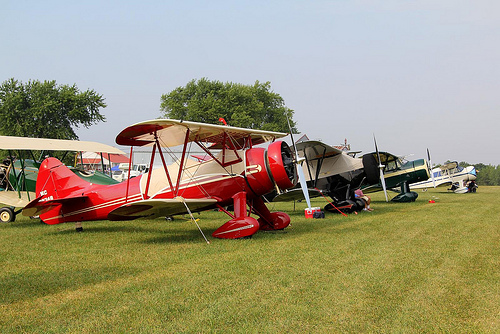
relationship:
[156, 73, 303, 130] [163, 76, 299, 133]
leaves on tree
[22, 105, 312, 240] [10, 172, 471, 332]
plane on ground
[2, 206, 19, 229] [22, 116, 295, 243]
back wheel on airplane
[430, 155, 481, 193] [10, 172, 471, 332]
airplane on ground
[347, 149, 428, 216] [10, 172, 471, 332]
airplane on ground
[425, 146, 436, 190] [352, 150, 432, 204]
propellor on airplane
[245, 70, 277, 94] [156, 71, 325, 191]
top of tree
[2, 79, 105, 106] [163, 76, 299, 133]
top of tree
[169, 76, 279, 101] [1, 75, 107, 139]
top of tree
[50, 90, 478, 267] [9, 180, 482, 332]
planes lined up on field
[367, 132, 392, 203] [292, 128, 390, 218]
propeller of plane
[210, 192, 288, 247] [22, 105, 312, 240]
landing gear of plane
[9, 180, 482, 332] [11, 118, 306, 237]
field of airplane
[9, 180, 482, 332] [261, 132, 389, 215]
field of planes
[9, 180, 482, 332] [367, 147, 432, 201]
field of airplane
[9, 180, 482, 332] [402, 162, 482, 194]
field of airplane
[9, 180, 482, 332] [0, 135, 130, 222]
field of airplane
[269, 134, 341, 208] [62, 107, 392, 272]
propeller on plane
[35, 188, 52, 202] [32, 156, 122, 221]
writing on tail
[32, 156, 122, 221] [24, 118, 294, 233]
tail of plane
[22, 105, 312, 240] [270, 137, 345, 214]
plane with propeller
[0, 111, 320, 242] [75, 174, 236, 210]
plane with stripes